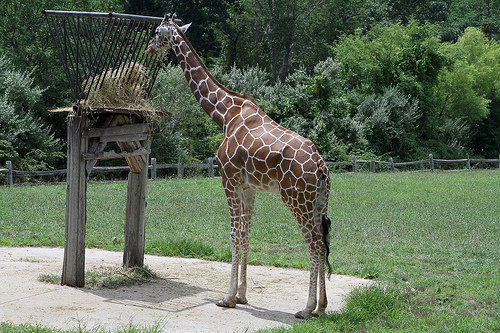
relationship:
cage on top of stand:
[53, 25, 166, 108] [60, 111, 150, 298]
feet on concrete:
[214, 291, 259, 318] [15, 263, 314, 329]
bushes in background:
[229, 73, 401, 151] [7, 17, 482, 161]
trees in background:
[202, 0, 392, 109] [7, 17, 482, 161]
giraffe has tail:
[156, 30, 352, 287] [321, 178, 335, 273]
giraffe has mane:
[156, 30, 352, 287] [178, 30, 264, 102]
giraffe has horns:
[156, 30, 352, 287] [162, 10, 178, 24]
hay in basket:
[92, 68, 139, 95] [61, 34, 166, 102]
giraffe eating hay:
[156, 30, 352, 287] [92, 68, 139, 95]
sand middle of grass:
[40, 284, 210, 325] [329, 175, 496, 261]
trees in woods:
[202, 0, 392, 109] [140, 16, 483, 140]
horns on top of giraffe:
[162, 10, 178, 24] [156, 30, 352, 287]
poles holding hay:
[59, 158, 155, 282] [92, 68, 139, 95]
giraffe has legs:
[156, 30, 352, 287] [226, 201, 329, 326]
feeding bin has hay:
[49, 5, 167, 111] [92, 68, 139, 95]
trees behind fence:
[202, 0, 392, 109] [145, 138, 500, 185]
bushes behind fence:
[229, 73, 401, 151] [145, 138, 500, 185]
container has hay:
[49, 5, 167, 111] [92, 68, 139, 95]